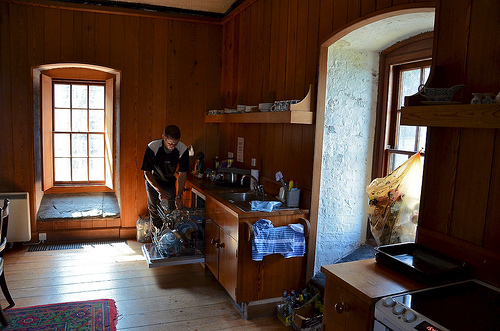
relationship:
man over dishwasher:
[144, 128, 186, 203] [192, 197, 205, 207]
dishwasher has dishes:
[192, 197, 205, 207] [158, 213, 194, 245]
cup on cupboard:
[269, 100, 281, 110] [205, 115, 307, 127]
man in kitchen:
[144, 128, 186, 203] [23, 6, 479, 253]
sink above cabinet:
[230, 193, 257, 205] [207, 206, 232, 289]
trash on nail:
[370, 183, 410, 245] [423, 145, 425, 153]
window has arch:
[54, 80, 106, 179] [47, 61, 113, 75]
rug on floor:
[21, 296, 124, 330] [21, 256, 141, 294]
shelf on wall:
[401, 105, 493, 127] [434, 132, 492, 226]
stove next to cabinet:
[377, 303, 402, 330] [325, 271, 370, 330]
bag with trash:
[405, 172, 415, 187] [370, 183, 410, 245]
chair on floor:
[2, 207, 6, 286] [21, 256, 141, 294]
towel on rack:
[254, 232, 297, 252] [305, 221, 314, 233]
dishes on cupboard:
[232, 103, 247, 115] [205, 115, 307, 127]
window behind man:
[54, 80, 106, 179] [144, 128, 186, 203]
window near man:
[386, 65, 409, 157] [144, 128, 186, 203]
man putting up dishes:
[144, 128, 186, 203] [158, 213, 194, 245]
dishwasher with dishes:
[192, 197, 205, 207] [158, 213, 194, 245]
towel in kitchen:
[254, 232, 297, 252] [23, 6, 479, 253]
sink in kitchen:
[230, 193, 257, 205] [23, 6, 479, 253]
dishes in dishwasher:
[158, 213, 194, 245] [192, 197, 205, 207]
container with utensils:
[289, 190, 302, 208] [276, 173, 291, 186]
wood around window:
[46, 77, 53, 194] [54, 80, 106, 179]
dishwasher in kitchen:
[192, 197, 205, 207] [23, 6, 479, 253]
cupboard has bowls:
[205, 115, 307, 127] [257, 102, 271, 112]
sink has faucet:
[230, 193, 257, 205] [255, 186, 264, 196]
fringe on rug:
[112, 302, 120, 326] [21, 296, 124, 330]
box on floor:
[293, 311, 310, 330] [21, 256, 141, 294]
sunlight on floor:
[95, 244, 129, 259] [21, 256, 141, 294]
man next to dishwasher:
[144, 128, 186, 203] [192, 197, 205, 207]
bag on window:
[405, 172, 415, 187] [386, 65, 409, 157]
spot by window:
[43, 194, 113, 217] [54, 80, 106, 179]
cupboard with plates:
[205, 115, 307, 127] [214, 107, 229, 115]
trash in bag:
[370, 183, 410, 245] [405, 172, 415, 187]